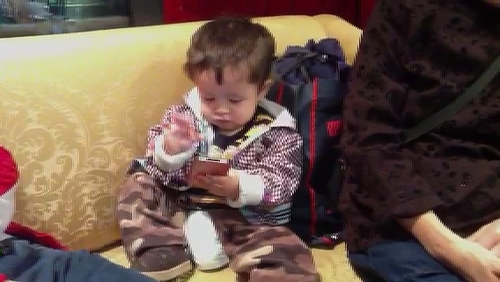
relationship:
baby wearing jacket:
[114, 15, 318, 280] [125, 85, 304, 225]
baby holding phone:
[114, 15, 318, 280] [181, 150, 229, 190]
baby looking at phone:
[114, 15, 318, 280] [186, 154, 230, 189]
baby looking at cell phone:
[114, 15, 318, 280] [189, 156, 227, 189]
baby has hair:
[114, 15, 318, 280] [184, 16, 274, 93]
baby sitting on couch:
[114, 15, 318, 280] [3, 8, 377, 280]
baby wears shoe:
[114, 15, 318, 280] [128, 240, 193, 280]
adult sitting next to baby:
[346, 5, 498, 280] [114, 15, 318, 280]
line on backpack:
[309, 78, 318, 226] [263, 37, 350, 249]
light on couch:
[5, 29, 140, 69] [3, 8, 377, 280]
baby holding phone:
[114, 15, 318, 280] [175, 148, 233, 198]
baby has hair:
[114, 15, 318, 280] [178, 10, 287, 97]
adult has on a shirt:
[339, 0, 500, 282] [341, 0, 496, 255]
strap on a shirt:
[386, 58, 498, 156] [341, 0, 496, 255]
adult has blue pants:
[339, 0, 500, 282] [322, 234, 437, 278]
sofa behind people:
[7, 32, 422, 214] [114, 9, 498, 280]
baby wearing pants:
[114, 15, 318, 280] [125, 181, 311, 274]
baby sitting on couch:
[119, 15, 321, 280] [3, 8, 377, 280]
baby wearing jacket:
[114, 15, 318, 280] [90, 67, 360, 230]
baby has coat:
[114, 15, 318, 280] [127, 85, 303, 225]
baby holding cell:
[114, 15, 318, 280] [179, 149, 233, 193]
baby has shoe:
[114, 15, 318, 280] [130, 243, 191, 280]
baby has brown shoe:
[114, 15, 318, 280] [126, 240, 199, 279]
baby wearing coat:
[114, 15, 318, 280] [125, 85, 305, 224]